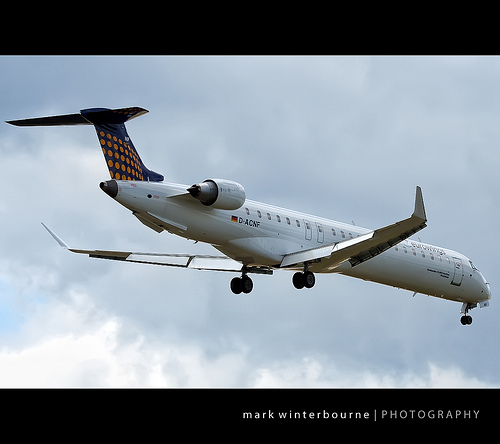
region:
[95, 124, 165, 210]
orange dots on the tail of a plane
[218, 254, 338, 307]
wheels on a plane out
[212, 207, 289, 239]
i identifiers on the plane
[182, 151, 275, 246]
engine on the plane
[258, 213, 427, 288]
wings of the plane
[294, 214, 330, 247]
emergency doors on the plane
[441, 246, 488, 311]
door to the plane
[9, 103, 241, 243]
blue tail to the plane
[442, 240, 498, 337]
Nose of the plane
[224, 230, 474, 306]
wheels of the plane ready for landing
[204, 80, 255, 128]
this is the sky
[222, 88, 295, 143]
the sky is blue in color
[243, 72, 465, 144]
the sky is full of clouds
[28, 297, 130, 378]
the clouds are white in color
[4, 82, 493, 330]
this is an airplane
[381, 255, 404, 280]
the airplane is white in color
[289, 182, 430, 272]
this is a wing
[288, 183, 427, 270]
the wing is long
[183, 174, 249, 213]
this is a propeller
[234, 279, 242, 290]
the wheels are small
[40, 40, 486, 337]
an airplane in the air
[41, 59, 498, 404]
an airplane in the sky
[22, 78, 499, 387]
a plane in the air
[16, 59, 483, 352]
a plane in the sky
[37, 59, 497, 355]
a white plane in the sky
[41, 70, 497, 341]
a white plane in the air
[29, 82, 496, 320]
a white airplane in the air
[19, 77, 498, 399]
a white airplane in the sky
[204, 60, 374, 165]
a blue cloudy sky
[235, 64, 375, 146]
a blue sky with clouds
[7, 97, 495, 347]
the plane in the air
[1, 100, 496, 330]
the plane is flying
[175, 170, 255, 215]
the engine on the plane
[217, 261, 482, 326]
the landing gear is down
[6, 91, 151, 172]
the tail of plane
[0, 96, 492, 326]
the plane is white blue and orange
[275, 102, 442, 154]
the clouds in the sky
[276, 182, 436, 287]
the wing of the plane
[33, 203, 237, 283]
the wing of the plane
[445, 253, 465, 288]
the hatch on the plane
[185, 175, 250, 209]
an engine on a jet plane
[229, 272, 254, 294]
landing wheels on a plane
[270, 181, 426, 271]
a wing on a jet plane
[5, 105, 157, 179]
the tail of a plane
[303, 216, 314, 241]
the door on a plane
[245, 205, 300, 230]
a row of windows on a plane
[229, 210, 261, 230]
an emblem on a plane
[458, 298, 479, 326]
the front wheel on a plane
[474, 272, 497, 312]
the nose of a plane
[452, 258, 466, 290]
a door on the front of the plane